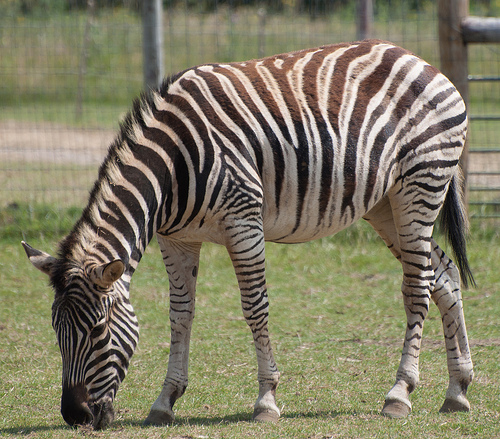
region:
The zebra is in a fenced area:
[17, 22, 487, 432]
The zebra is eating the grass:
[28, 19, 476, 437]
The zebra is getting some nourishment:
[22, 25, 488, 436]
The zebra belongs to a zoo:
[5, 10, 495, 432]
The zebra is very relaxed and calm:
[13, 27, 489, 435]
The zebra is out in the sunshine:
[0, 25, 497, 431]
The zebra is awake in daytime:
[21, 16, 492, 436]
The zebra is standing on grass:
[5, 25, 492, 435]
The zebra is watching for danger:
[2, 22, 489, 433]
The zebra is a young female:
[3, 25, 494, 435]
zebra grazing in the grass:
[13, 30, 481, 423]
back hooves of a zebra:
[376, 396, 474, 424]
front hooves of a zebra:
[146, 391, 286, 429]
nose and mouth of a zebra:
[55, 392, 122, 427]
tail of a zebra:
[444, 164, 483, 294]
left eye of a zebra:
[85, 312, 115, 340]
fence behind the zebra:
[12, 68, 95, 198]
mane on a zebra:
[49, 123, 151, 286]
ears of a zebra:
[16, 225, 144, 296]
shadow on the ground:
[182, 404, 248, 426]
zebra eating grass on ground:
[0, 37, 497, 436]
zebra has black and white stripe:
[16, 36, 489, 431]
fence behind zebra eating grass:
[2, 1, 494, 435]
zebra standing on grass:
[0, 40, 496, 435]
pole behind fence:
[1, 2, 496, 219]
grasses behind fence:
[2, 1, 494, 154]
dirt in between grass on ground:
[0, 114, 495, 436]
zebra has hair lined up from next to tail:
[17, 35, 482, 432]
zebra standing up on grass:
[4, 34, 495, 435]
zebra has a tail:
[10, 35, 480, 433]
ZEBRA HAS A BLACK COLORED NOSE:
[53, 360, 122, 432]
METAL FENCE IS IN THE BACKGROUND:
[11, 5, 498, 57]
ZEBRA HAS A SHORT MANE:
[43, 59, 201, 289]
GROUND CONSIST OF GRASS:
[0, 260, 493, 434]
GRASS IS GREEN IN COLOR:
[28, 226, 445, 431]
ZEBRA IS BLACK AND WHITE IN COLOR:
[4, 30, 487, 422]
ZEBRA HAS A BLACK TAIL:
[443, 131, 484, 287]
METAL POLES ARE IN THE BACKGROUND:
[136, 5, 171, 79]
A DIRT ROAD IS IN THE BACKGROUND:
[11, 110, 498, 194]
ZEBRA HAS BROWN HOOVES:
[149, 398, 491, 423]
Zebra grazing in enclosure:
[18, 34, 477, 428]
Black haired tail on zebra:
[446, 169, 481, 300]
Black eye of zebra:
[85, 319, 110, 344]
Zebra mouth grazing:
[87, 391, 123, 432]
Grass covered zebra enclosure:
[6, 218, 496, 438]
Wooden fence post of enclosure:
[431, 6, 468, 217]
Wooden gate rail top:
[460, 13, 499, 49]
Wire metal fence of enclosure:
[6, 5, 437, 219]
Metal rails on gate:
[459, 68, 499, 226]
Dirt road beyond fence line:
[8, 118, 495, 195]